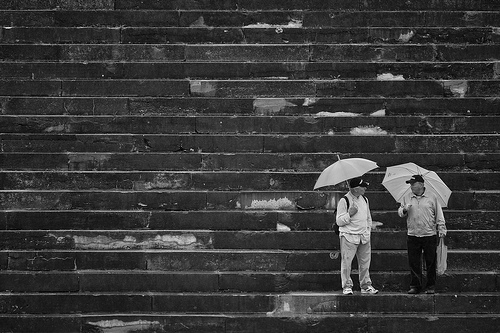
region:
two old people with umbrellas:
[313, 140, 450, 299]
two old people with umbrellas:
[307, 123, 465, 315]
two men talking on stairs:
[316, 139, 460, 296]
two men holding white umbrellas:
[310, 134, 462, 293]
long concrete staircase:
[30, 31, 277, 298]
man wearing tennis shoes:
[332, 175, 392, 310]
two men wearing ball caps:
[322, 171, 453, 300]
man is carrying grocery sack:
[400, 167, 466, 287]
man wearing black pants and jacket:
[387, 160, 451, 307]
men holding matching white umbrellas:
[312, 148, 473, 309]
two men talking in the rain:
[297, 141, 475, 313]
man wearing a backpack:
[310, 144, 395, 295]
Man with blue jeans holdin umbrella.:
[310, 148, 385, 297]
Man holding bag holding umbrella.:
[380, 155, 463, 297]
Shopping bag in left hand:
[432, 232, 451, 276]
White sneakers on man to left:
[336, 281, 386, 298]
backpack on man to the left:
[328, 193, 354, 236]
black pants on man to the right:
[403, 233, 441, 295]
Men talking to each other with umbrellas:
[303, 147, 455, 299]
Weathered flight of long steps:
[4, 7, 496, 325]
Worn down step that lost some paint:
[48, 230, 219, 257]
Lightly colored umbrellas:
[306, 148, 463, 220]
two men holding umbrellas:
[315, 148, 455, 298]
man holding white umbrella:
[382, 162, 454, 297]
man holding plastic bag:
[395, 171, 450, 296]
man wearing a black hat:
[330, 175, 377, 301]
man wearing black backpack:
[330, 175, 377, 295]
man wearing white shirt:
[330, 176, 379, 295]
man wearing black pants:
[397, 170, 449, 295]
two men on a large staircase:
[0, 0, 495, 332]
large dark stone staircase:
[0, 0, 498, 332]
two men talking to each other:
[312, 150, 456, 294]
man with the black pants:
[382, 163, 453, 293]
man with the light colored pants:
[312, 152, 377, 294]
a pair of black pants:
[406, 236, 434, 292]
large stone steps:
[3, 5, 498, 328]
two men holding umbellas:
[314, 154, 451, 297]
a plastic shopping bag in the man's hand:
[435, 233, 447, 274]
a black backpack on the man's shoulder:
[330, 195, 347, 236]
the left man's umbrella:
[312, 153, 377, 205]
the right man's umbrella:
[382, 163, 452, 209]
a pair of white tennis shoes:
[343, 287, 377, 294]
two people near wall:
[299, 142, 480, 320]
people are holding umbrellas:
[311, 123, 463, 268]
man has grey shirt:
[396, 187, 457, 258]